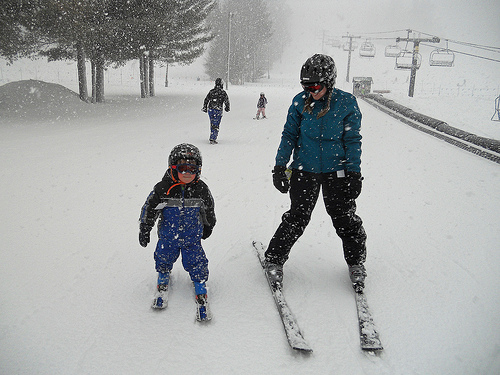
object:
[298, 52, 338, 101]
head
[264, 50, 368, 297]
adult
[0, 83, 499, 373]
slope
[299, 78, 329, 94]
ski goggles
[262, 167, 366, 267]
pants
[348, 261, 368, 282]
foot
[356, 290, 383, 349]
snow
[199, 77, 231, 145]
people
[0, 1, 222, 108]
tree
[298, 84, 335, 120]
hair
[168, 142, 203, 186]
cap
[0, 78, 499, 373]
ground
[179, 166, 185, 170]
eyes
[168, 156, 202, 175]
goggles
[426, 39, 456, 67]
lift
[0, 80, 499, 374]
snow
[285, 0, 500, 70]
sky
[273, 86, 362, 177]
jacket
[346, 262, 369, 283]
boots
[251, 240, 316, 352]
ski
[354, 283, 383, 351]
ski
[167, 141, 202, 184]
head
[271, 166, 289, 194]
glove hand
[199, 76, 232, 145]
adult person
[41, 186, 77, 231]
white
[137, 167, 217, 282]
ski suit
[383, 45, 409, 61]
ski car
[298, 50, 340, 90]
helmet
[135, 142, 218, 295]
child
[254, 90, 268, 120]
child